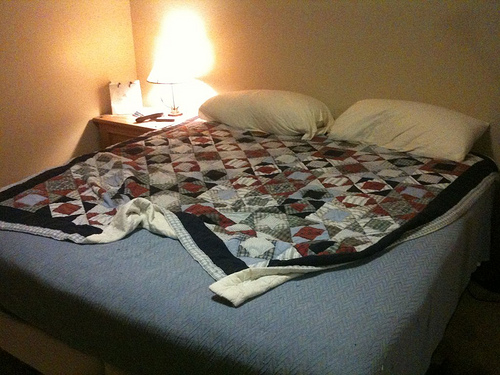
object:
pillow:
[198, 89, 336, 140]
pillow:
[327, 98, 490, 163]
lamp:
[146, 56, 189, 122]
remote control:
[135, 112, 174, 122]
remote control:
[156, 118, 176, 122]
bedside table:
[92, 113, 198, 149]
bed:
[0, 113, 500, 375]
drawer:
[109, 133, 137, 145]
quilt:
[0, 115, 500, 308]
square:
[302, 189, 327, 199]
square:
[203, 169, 227, 180]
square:
[323, 149, 345, 157]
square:
[432, 161, 458, 171]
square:
[234, 137, 255, 143]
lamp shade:
[153, 6, 216, 77]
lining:
[0, 115, 498, 277]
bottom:
[119, 253, 154, 298]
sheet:
[0, 184, 496, 374]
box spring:
[0, 313, 128, 375]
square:
[53, 203, 82, 215]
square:
[293, 226, 326, 240]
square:
[360, 181, 387, 191]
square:
[192, 136, 211, 143]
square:
[274, 154, 298, 164]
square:
[417, 173, 443, 183]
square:
[240, 236, 274, 258]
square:
[376, 167, 403, 177]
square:
[15, 193, 48, 207]